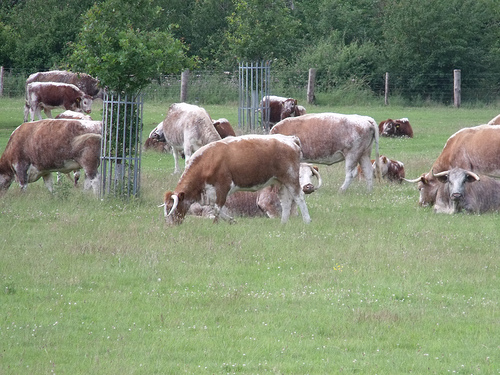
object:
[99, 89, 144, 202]
fence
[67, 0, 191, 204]
tree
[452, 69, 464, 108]
pole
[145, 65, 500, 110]
fence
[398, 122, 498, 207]
cow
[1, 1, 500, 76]
trees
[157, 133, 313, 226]
cow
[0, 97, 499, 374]
grass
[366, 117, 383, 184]
tail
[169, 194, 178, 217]
horn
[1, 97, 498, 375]
field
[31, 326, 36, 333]
flower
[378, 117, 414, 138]
cow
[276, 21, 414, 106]
bushes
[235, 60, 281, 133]
fence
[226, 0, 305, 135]
tree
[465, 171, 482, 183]
horn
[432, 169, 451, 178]
horn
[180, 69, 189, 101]
pole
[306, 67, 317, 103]
pole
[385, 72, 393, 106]
pole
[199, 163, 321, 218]
cow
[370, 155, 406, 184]
cow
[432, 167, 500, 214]
cow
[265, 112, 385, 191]
cow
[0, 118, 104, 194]
cow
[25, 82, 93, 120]
cow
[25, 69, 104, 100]
cow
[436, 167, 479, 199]
head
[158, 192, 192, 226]
head